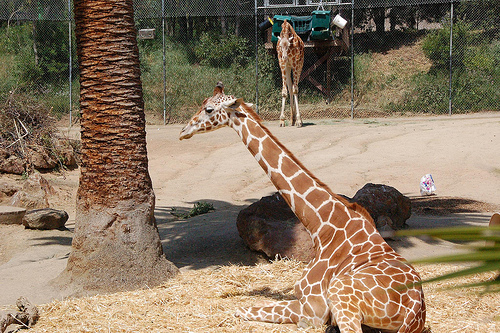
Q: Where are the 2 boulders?
A: Beside giraffe.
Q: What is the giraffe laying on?
A: Hay.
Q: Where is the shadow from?
A: Tree.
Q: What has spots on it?
A: Giraffe.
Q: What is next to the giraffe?
A: A tree.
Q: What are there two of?
A: Giraffes.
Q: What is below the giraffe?
A: The ground.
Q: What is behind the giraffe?
A: Fence.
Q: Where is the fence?
A: Behind the giraffe.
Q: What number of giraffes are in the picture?
A: 2.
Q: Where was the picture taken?
A: Zoo.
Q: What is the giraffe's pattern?
A: Spotted.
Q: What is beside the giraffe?
A: Tree.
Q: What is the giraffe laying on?
A: Grass.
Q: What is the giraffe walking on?
A: Dirt.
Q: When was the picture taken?
A: Afternoon.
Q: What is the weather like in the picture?
A: Sunny.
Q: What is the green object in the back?
A: Feeding basket.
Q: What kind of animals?
A: Giraffes.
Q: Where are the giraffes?
A: Zoo.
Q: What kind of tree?
A: Palm.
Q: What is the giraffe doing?
A: Laying down.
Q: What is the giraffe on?
A: Straw.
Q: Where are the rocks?
A: On the ground.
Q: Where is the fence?
A: By the giraffe.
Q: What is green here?
A: Trees.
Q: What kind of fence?
A: Chain link.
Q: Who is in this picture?
A: Giraffes.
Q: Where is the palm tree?
A: Next to the giraffes.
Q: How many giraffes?
A: 2.